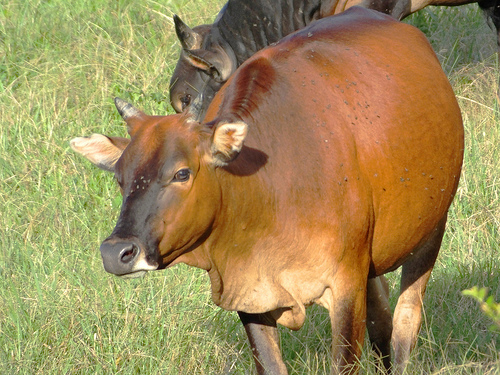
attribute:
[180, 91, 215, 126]
horn — black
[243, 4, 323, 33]
skin — wrinkled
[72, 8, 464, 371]
skin — smooth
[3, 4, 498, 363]
grass — green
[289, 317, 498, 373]
grass — tall, thin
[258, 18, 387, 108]
back — brown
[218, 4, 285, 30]
neck — black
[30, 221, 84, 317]
grass — green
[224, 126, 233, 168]
hair — brown